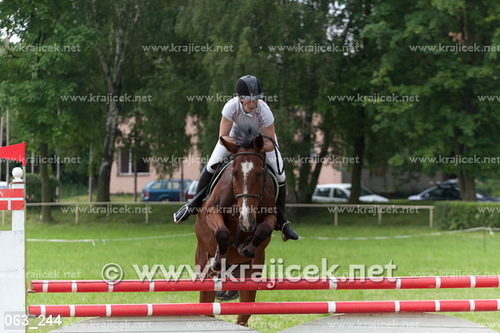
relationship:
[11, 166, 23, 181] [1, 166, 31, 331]
knob on fence post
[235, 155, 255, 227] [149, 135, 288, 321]
fur on horse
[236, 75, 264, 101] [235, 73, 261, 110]
helmet on head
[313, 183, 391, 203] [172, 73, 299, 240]
car behind rider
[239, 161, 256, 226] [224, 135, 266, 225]
stripe on head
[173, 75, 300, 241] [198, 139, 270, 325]
person riding on horse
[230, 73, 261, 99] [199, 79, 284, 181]
helmet on jockey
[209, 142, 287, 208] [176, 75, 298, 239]
pants on jockey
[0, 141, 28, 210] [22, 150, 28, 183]
flag on pole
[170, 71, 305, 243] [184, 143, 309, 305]
person riding horse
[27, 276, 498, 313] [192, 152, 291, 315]
obstacle for horse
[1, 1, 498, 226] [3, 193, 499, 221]
trees lining a street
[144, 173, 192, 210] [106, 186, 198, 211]
car parked on street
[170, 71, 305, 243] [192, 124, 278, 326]
person riding a horse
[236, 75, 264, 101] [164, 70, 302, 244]
helmet on rider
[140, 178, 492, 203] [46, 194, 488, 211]
cars are on road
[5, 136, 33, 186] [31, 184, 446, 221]
flag on field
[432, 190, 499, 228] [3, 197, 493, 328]
bushes are on ground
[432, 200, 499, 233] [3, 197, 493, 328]
bushes are on ground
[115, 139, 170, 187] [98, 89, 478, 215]
window in a building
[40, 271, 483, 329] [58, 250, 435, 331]
marks are on a obstacle